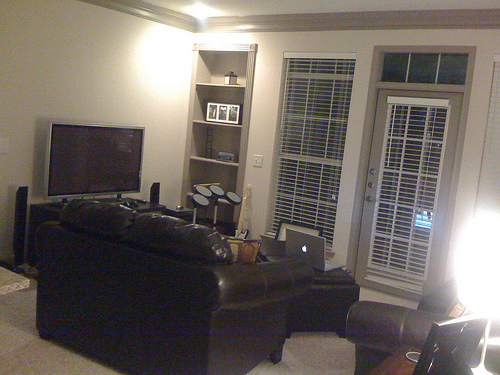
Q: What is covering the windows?
A: Blinds.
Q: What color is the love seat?
A: Brown.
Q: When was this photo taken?
A: At night.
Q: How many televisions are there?
A: One.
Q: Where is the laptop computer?
A: On the ottoman by the door.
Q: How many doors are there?
A: One.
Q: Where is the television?
A: Against the wall.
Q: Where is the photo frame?
A: On the table in the right corner.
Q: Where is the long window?
A: To the left of the door.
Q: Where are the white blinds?
A: Covering the windows.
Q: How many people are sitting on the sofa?
A: Zero.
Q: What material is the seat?
A: Leather.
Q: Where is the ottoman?
A: In front of loveseat.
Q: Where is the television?
A: On stand.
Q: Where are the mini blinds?
A: On window and door.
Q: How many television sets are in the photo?
A: One.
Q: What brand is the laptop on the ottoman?
A: Apple.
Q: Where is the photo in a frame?
A: On shelves.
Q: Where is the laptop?
A: On the ottoman.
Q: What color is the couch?
A: Black.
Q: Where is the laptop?
A: On the ottoman.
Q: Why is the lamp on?
A: Because it is dark outside.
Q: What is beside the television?
A: Shelves.